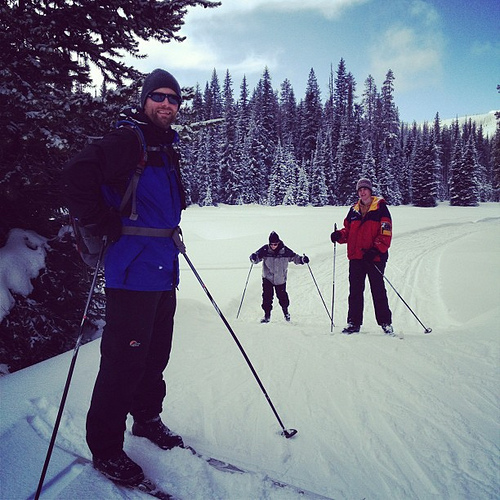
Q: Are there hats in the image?
A: Yes, there is a hat.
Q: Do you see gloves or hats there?
A: Yes, there is a hat.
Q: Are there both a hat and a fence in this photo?
A: No, there is a hat but no fences.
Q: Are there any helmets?
A: No, there are no helmets.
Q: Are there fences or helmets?
A: No, there are no helmets or fences.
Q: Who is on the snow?
A: The people are on the snow.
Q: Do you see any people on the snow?
A: Yes, there are people on the snow.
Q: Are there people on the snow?
A: Yes, there are people on the snow.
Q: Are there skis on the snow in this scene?
A: No, there are people on the snow.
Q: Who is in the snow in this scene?
A: The people are in the snow.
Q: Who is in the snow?
A: The people are in the snow.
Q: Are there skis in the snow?
A: No, there are people in the snow.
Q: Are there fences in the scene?
A: No, there are no fences.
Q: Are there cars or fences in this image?
A: No, there are no fences or cars.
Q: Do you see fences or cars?
A: No, there are no fences or cars.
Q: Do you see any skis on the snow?
A: No, there are people on the snow.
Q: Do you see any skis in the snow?
A: No, there are people in the snow.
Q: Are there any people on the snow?
A: Yes, there are people on the snow.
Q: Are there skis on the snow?
A: No, there are people on the snow.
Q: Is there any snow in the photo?
A: Yes, there is snow.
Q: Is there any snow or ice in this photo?
A: Yes, there is snow.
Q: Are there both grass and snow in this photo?
A: No, there is snow but no grass.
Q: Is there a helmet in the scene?
A: No, there are no helmets.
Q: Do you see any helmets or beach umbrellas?
A: No, there are no helmets or beach umbrellas.